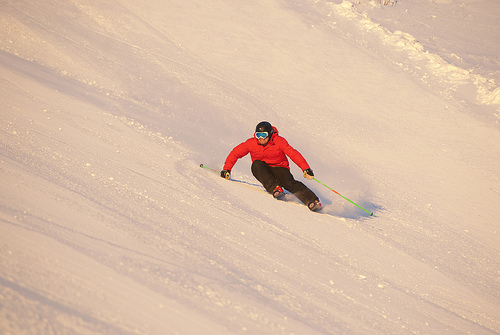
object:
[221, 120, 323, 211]
man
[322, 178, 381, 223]
stick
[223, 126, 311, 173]
jacket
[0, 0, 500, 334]
snow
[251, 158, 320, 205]
trouser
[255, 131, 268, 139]
goggles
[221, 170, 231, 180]
gloves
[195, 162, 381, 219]
poles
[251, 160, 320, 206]
pants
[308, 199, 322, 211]
boots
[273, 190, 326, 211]
skis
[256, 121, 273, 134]
hat